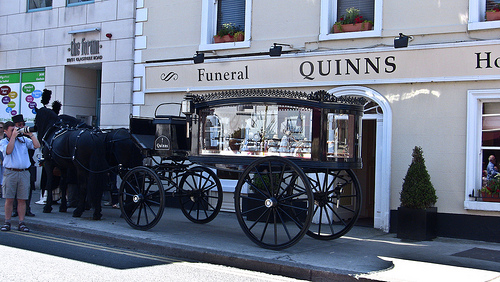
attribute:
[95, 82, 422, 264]
carriage — black, horse-drawn, white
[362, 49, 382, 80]
letter — black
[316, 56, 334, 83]
letter — black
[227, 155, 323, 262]
wheel — black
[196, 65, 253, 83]
letter — black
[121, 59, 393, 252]
carriage — Clear 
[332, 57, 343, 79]
letter — black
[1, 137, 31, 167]
shirt — white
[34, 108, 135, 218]
horse — black